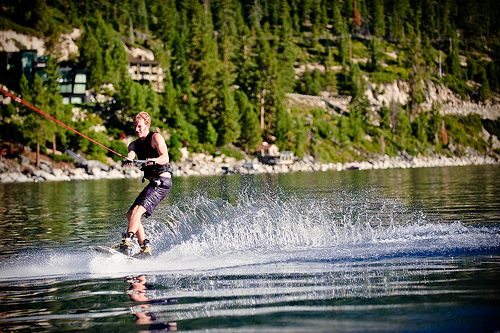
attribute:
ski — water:
[97, 232, 139, 268]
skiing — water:
[85, 230, 157, 271]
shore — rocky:
[188, 138, 316, 176]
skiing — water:
[88, 219, 165, 262]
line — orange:
[23, 93, 106, 144]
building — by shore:
[3, 49, 131, 153]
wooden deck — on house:
[116, 65, 166, 87]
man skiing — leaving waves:
[119, 109, 179, 263]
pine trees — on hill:
[7, 4, 386, 154]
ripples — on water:
[323, 251, 431, 301]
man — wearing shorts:
[131, 179, 171, 211]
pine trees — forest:
[133, 18, 325, 158]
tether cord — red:
[8, 90, 102, 154]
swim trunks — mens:
[129, 176, 172, 220]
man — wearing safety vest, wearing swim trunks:
[122, 110, 183, 266]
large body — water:
[235, 175, 484, 323]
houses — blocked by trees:
[1, 17, 184, 146]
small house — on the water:
[259, 139, 294, 169]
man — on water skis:
[110, 108, 177, 277]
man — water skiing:
[118, 107, 173, 261]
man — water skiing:
[124, 110, 173, 261]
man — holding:
[106, 109, 176, 265]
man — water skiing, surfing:
[111, 106, 180, 258]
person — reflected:
[113, 108, 180, 270]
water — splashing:
[0, 149, 495, 330]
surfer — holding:
[115, 108, 175, 264]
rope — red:
[3, 80, 126, 161]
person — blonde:
[108, 107, 182, 267]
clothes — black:
[119, 131, 177, 217]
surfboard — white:
[79, 230, 156, 267]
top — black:
[117, 131, 176, 174]